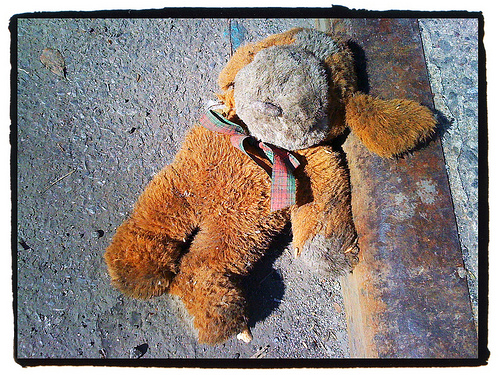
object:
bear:
[103, 26, 442, 346]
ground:
[16, 17, 480, 362]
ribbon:
[198, 108, 302, 213]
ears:
[344, 89, 439, 158]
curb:
[325, 17, 480, 361]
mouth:
[250, 99, 284, 118]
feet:
[168, 253, 249, 348]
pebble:
[126, 344, 144, 360]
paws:
[295, 230, 359, 280]